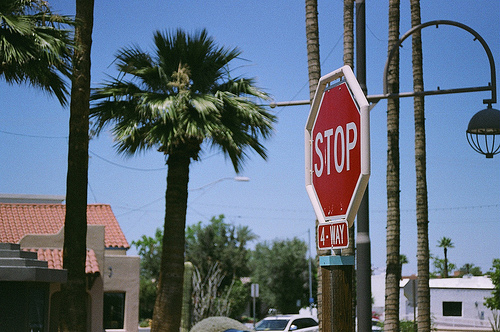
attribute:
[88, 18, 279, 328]
palm tree — green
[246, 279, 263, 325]
pole — metal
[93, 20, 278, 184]
giraffe — nowhere to be seen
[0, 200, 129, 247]
roof — red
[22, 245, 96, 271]
roof — red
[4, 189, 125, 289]
tile — red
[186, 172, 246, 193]
street light — white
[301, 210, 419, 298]
post — small, gray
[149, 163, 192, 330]
trunk — thick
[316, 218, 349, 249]
sign — red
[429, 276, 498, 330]
building — white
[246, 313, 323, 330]
car — small, white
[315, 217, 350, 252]
sign — small, red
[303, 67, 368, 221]
stop sign — white, red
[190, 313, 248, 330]
rock — large, gray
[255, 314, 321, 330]
white car — is white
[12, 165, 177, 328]
building — white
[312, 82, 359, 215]
stop sign — is red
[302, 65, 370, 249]
white border — is white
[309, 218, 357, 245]
sign — small, red, white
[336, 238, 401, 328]
pole — skinny, gray, metal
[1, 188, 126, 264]
tile roof — red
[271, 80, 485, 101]
pole — metal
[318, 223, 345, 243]
4-way — white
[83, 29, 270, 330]
palm tree — large